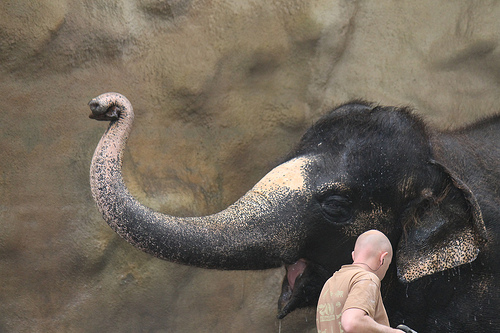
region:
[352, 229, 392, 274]
the head of a person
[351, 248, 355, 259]
the ear of a person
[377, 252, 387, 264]
the ear of a person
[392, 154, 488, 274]
the ear of an elephant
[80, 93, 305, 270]
the trunk of an elephant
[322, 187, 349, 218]
the eye of an elephant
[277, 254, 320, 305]
the open mouth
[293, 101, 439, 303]
the grey head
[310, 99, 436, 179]
the black hair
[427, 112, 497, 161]
the back of an elephant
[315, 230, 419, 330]
Bald man wearing headphones.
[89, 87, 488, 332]
Elephant near a handler.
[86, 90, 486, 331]
Elephant raising his trunk.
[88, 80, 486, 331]
Elephant holding something in his trunk.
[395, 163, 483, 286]
Elephant ear dripping with water.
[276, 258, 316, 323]
Open elephant mouth with water dripping from it.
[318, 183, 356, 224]
Open elephant eye.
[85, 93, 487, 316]
Elephant trunk and ear with variety of pigmentations.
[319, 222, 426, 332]
Elephant handler standing near a small elephant.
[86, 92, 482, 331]
Young elephant holding his trunk up.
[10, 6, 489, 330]
an elephant is in an enclosure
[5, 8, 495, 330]
the rock wall is in the enclosure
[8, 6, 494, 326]
the rock wall is man made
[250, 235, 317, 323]
the elephant's mouth is open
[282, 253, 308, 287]
a pink tongue is protruding from the elephant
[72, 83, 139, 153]
the elephant has an object in its trunk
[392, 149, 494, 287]
the elephant has small ears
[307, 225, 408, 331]
a man is next to the elephant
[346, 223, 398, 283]
the trainer has a bald head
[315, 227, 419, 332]
the man has a hose in his hand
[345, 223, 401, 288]
Shaved head on person.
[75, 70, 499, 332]
Elephant behind the man.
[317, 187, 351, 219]
Black eye on the elephant.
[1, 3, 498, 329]
Rock wall behind the elephant.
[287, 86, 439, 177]
Black hair on the elephant.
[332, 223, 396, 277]
Earbuds in the ear.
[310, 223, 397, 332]
Brown shirt on the person.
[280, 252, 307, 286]
Tongue on the elephant.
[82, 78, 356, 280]
Trunk on the elephant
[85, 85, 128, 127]
Brown object held in trunk.